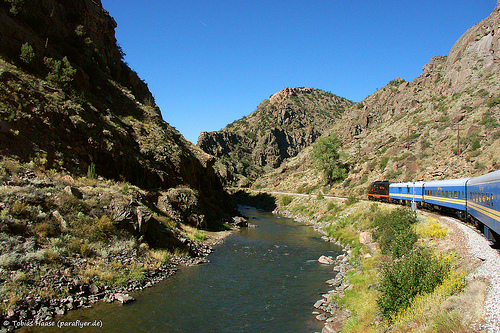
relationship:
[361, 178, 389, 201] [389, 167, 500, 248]
locomotive pulling cars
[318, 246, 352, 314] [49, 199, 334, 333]
rocks by stream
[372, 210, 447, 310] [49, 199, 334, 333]
shrub brush by stream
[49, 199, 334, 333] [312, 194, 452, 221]
stream near tracks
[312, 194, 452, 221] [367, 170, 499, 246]
tracks of train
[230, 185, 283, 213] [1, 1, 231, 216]
shadow of hill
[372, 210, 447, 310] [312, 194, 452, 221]
shrub brush by tracks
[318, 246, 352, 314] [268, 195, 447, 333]
rocks on shore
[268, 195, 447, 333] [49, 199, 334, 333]
shore of stream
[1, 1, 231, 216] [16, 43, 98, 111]
hill with bushes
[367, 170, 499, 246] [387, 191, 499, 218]
train with stripe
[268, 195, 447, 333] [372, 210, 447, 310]
shore with shrub brush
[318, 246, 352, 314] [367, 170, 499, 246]
rocks next to train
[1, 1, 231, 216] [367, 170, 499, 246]
hill above train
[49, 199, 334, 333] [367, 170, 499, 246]
stream next to train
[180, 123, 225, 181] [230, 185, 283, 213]
rocks casting shadow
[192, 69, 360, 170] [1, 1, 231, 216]
hill behind hill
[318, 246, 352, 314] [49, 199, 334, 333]
rocks in stream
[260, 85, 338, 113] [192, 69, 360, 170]
top of hill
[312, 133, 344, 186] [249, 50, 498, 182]
tree on hill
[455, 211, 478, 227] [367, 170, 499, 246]
wheels on train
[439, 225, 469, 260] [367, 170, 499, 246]
dirt next to train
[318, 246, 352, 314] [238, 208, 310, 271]
rocks next to water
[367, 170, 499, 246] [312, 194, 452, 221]
train on tracks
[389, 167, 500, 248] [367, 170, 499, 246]
cars of train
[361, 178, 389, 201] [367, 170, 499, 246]
locomotive on train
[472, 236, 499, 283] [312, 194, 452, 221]
gravel along tracks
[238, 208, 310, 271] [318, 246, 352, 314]
water has rocks